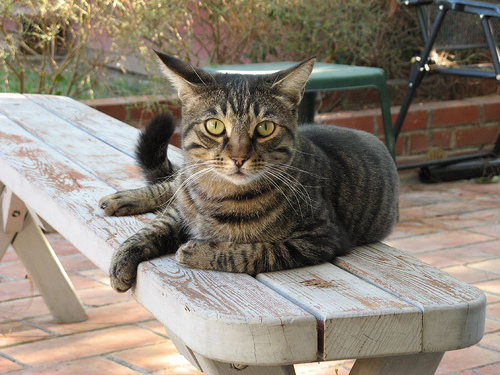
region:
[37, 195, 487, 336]
bricks on the ground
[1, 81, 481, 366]
a wooden bench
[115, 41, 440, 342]
a cat laying on a bench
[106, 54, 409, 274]
a black and brown cat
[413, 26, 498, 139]
a chair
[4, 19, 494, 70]
bushes behind the bricks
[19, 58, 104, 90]
grass behind the bushes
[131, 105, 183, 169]
the tail of the cat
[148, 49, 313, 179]
the face of the cat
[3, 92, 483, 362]
a bench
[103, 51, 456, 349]
a cat laying on a bench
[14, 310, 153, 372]
bricks under the bench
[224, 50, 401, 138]
a green table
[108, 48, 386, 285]
a cat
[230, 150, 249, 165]
the nose of the cat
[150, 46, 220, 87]
the ear of the cat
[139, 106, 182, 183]
the tail of the cat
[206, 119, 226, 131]
the green eye of the cat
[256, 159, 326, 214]
the white whiskers on the cat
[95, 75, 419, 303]
the cat is laying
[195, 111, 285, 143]
eyes of the cat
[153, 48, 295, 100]
ears of the cat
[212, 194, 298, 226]
stripes on the cat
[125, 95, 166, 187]
tail of the cat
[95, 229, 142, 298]
paw of the cat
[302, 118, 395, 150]
back of the cat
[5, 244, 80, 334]
leg of the table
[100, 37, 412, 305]
This is a cat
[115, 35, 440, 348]
This is a cat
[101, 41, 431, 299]
This is a cat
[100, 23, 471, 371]
This is a cat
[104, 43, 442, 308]
This is a cat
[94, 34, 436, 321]
This is a cat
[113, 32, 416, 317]
This is a cat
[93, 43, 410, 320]
This is a cat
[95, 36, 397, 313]
This is a cat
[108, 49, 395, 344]
This is a cat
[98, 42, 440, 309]
This is a cat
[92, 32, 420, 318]
This is a cat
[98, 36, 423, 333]
This is a cat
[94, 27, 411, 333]
This is a cat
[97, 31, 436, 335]
This is a cat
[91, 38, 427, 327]
This is a cat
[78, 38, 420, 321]
This is a cat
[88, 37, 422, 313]
This is a cat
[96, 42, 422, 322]
This is a cat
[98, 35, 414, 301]
This is a cat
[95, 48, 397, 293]
A gray cat on a bench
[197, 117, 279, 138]
Yellow eyes on a cat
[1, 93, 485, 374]
A wooden bench on a patio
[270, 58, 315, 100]
An ear on a cat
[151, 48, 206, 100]
An ear on a cat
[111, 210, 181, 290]
A front leg on a cat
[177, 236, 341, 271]
A front leg on a cat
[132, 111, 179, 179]
A cat tail with a black tip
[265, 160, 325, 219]
White whiskers on a cat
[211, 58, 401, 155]
A green table on a patio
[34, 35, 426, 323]
grey cat sitting on wood bench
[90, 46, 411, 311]
green table behind grey cat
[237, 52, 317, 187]
yellow eye on grey cat